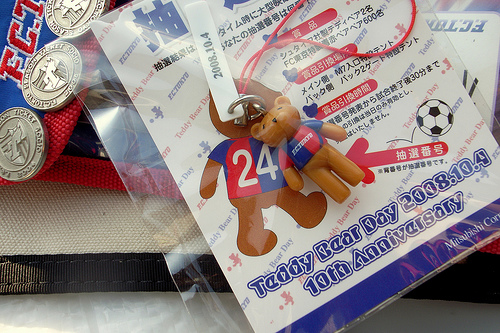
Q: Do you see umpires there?
A: No, there are no umpires.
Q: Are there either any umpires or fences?
A: No, there are no umpires or fences.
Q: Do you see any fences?
A: No, there are no fences.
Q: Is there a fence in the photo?
A: No, there are no fences.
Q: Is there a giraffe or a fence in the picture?
A: No, there are no fences or giraffes.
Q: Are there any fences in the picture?
A: No, there are no fences.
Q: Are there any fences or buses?
A: No, there are no fences or buses.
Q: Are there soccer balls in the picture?
A: Yes, there is a soccer ball.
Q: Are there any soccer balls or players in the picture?
A: Yes, there is a soccer ball.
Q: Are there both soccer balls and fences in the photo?
A: No, there is a soccer ball but no fences.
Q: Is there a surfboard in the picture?
A: No, there are no surfboards.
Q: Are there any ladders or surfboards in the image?
A: No, there are no surfboards or ladders.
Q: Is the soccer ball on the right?
A: Yes, the soccer ball is on the right of the image.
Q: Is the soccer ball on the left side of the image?
A: No, the soccer ball is on the right of the image.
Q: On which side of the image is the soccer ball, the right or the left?
A: The soccer ball is on the right of the image.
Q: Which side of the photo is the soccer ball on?
A: The soccer ball is on the right of the image.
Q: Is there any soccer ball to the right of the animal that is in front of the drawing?
A: Yes, there is a soccer ball to the right of the bear.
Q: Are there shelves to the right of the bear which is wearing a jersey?
A: No, there is a soccer ball to the right of the bear.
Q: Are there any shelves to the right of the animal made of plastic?
A: No, there is a soccer ball to the right of the bear.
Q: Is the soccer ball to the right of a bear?
A: Yes, the soccer ball is to the right of a bear.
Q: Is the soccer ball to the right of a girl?
A: No, the soccer ball is to the right of a bear.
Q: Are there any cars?
A: No, there are no cars.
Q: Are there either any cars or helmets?
A: No, there are no cars or helmets.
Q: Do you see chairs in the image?
A: No, there are no chairs.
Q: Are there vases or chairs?
A: No, there are no chairs or vases.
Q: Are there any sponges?
A: No, there are no sponges.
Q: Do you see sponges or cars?
A: No, there are no sponges or cars.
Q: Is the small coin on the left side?
A: Yes, the coin is on the left of the image.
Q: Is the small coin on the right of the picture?
A: No, the coin is on the left of the image.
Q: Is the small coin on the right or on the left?
A: The coin is on the left of the image.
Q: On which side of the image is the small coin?
A: The coin is on the left of the image.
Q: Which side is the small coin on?
A: The coin is on the left of the image.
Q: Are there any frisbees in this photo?
A: No, there are no frisbees.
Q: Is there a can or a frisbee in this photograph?
A: No, there are no frisbees or cans.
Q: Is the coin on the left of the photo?
A: Yes, the coin is on the left of the image.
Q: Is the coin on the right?
A: No, the coin is on the left of the image.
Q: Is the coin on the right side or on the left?
A: The coin is on the left of the image.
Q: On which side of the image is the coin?
A: The coin is on the left of the image.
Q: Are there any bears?
A: Yes, there is a bear.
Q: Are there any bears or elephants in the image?
A: Yes, there is a bear.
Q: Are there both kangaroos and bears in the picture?
A: No, there is a bear but no kangaroos.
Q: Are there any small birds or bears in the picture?
A: Yes, there is a small bear.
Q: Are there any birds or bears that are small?
A: Yes, the bear is small.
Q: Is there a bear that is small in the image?
A: Yes, there is a small bear.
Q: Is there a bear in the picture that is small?
A: Yes, there is a bear that is small.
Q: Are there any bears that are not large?
A: Yes, there is a small bear.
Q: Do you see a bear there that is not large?
A: Yes, there is a small bear.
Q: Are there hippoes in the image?
A: No, there are no hippoes.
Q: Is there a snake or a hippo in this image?
A: No, there are no hippoes or snakes.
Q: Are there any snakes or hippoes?
A: No, there are no hippoes or snakes.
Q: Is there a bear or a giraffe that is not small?
A: No, there is a bear but it is small.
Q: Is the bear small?
A: Yes, the bear is small.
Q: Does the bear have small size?
A: Yes, the bear is small.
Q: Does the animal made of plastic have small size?
A: Yes, the bear is small.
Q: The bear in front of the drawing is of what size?
A: The bear is small.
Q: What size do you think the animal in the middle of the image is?
A: The bear is small.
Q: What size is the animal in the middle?
A: The bear is small.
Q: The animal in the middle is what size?
A: The bear is small.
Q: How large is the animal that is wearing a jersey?
A: The bear is small.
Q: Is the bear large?
A: No, the bear is small.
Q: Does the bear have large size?
A: No, the bear is small.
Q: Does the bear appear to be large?
A: No, the bear is small.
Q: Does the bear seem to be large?
A: No, the bear is small.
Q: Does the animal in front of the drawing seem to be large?
A: No, the bear is small.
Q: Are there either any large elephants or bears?
A: No, there is a bear but it is small.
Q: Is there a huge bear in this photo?
A: No, there is a bear but it is small.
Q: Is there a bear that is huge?
A: No, there is a bear but it is small.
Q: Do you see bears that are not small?
A: No, there is a bear but it is small.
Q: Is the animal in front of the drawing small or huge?
A: The bear is small.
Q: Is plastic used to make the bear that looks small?
A: Yes, the bear is made of plastic.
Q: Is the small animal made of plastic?
A: Yes, the bear is made of plastic.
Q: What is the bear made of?
A: The bear is made of plastic.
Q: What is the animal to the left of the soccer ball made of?
A: The bear is made of plastic.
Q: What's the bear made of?
A: The bear is made of plastic.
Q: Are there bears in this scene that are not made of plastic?
A: No, there is a bear but it is made of plastic.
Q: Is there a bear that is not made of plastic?
A: No, there is a bear but it is made of plastic.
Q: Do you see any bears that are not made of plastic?
A: No, there is a bear but it is made of plastic.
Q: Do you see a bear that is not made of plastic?
A: No, there is a bear but it is made of plastic.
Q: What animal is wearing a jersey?
A: The bear is wearing a jersey.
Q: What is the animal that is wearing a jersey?
A: The animal is a bear.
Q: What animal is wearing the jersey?
A: The animal is a bear.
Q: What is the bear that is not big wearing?
A: The bear is wearing a jersey.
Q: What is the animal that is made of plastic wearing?
A: The bear is wearing a jersey.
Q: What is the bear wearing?
A: The bear is wearing a jersey.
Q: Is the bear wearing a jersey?
A: Yes, the bear is wearing a jersey.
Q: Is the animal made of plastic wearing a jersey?
A: Yes, the bear is wearing a jersey.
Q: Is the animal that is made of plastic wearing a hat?
A: No, the bear is wearing a jersey.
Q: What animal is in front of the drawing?
A: The bear is in front of the drawing.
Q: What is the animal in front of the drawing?
A: The animal is a bear.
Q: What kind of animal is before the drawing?
A: The animal is a bear.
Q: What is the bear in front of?
A: The bear is in front of the drawing.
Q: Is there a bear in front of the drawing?
A: Yes, there is a bear in front of the drawing.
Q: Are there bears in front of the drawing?
A: Yes, there is a bear in front of the drawing.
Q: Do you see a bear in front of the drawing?
A: Yes, there is a bear in front of the drawing.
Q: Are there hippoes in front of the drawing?
A: No, there is a bear in front of the drawing.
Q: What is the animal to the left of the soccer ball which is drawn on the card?
A: The animal is a bear.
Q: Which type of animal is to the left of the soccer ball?
A: The animal is a bear.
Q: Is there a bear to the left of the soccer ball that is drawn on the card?
A: Yes, there is a bear to the left of the soccer ball.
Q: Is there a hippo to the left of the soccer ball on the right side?
A: No, there is a bear to the left of the soccer ball.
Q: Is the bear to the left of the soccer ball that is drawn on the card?
A: Yes, the bear is to the left of the soccer ball.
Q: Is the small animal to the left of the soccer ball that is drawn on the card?
A: Yes, the bear is to the left of the soccer ball.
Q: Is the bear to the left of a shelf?
A: No, the bear is to the left of the soccer ball.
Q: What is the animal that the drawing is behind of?
A: The animal is a bear.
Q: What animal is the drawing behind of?
A: The drawing is behind the bear.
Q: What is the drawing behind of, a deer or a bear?
A: The drawing is behind a bear.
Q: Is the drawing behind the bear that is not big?
A: Yes, the drawing is behind the bear.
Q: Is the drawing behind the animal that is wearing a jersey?
A: Yes, the drawing is behind the bear.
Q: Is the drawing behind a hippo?
A: No, the drawing is behind the bear.